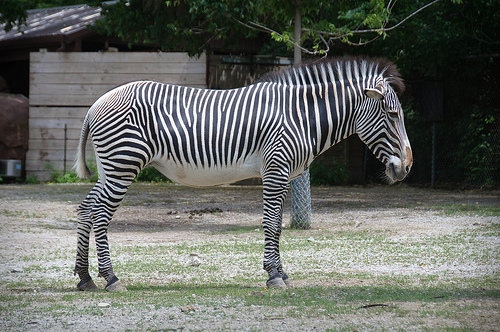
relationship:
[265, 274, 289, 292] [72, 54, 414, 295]
hooves on zebra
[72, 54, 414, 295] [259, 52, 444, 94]
zebra has hair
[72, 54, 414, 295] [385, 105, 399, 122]
zebra has eye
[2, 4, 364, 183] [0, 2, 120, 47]
building has roof